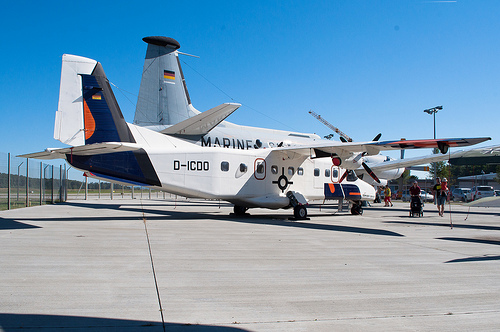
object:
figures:
[174, 160, 210, 171]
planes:
[14, 35, 492, 219]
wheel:
[289, 217, 310, 221]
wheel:
[344, 214, 359, 215]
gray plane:
[175, 216, 239, 218]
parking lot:
[1, 197, 499, 330]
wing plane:
[52, 53, 135, 148]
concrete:
[22, 232, 117, 287]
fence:
[0, 152, 187, 212]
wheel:
[287, 218, 311, 221]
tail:
[14, 53, 142, 173]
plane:
[1, 201, 406, 236]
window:
[325, 169, 330, 177]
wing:
[224, 220, 405, 237]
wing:
[159, 102, 241, 141]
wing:
[15, 140, 141, 160]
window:
[221, 161, 229, 171]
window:
[240, 163, 246, 173]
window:
[271, 165, 279, 174]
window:
[288, 166, 294, 175]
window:
[314, 168, 319, 176]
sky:
[199, 5, 493, 65]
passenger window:
[271, 165, 279, 174]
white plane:
[14, 35, 492, 220]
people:
[409, 180, 425, 217]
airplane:
[15, 35, 491, 220]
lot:
[4, 188, 499, 330]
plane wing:
[50, 202, 405, 237]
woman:
[409, 180, 424, 217]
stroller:
[409, 180, 424, 218]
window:
[257, 161, 264, 173]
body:
[15, 35, 492, 219]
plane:
[62, 222, 229, 265]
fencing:
[339, 132, 405, 193]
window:
[257, 162, 264, 174]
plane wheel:
[294, 205, 308, 219]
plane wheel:
[351, 205, 363, 215]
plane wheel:
[233, 204, 246, 216]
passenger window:
[221, 161, 229, 172]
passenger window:
[221, 161, 229, 171]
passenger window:
[271, 165, 278, 175]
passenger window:
[288, 166, 294, 175]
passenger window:
[314, 168, 320, 176]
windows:
[220, 161, 338, 178]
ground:
[11, 249, 383, 329]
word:
[201, 136, 252, 150]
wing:
[272, 137, 491, 159]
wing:
[51, 53, 142, 147]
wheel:
[234, 203, 247, 216]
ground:
[2, 226, 460, 330]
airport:
[0, 149, 499, 332]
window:
[297, 167, 303, 175]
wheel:
[294, 204, 307, 220]